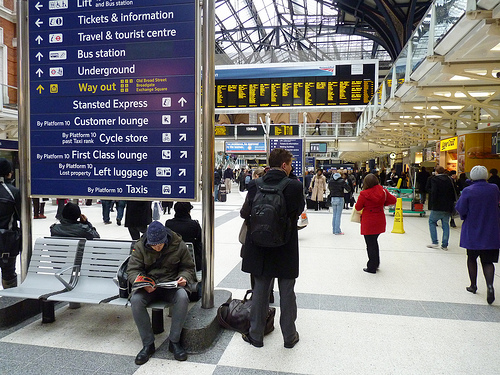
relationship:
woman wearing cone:
[351, 165, 399, 288] [390, 198, 405, 235]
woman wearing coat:
[449, 164, 497, 304] [456, 182, 498, 250]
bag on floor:
[217, 290, 275, 336] [4, 181, 497, 373]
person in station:
[453, 162, 497, 308] [2, 1, 499, 371]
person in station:
[239, 143, 309, 348] [2, 1, 499, 371]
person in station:
[121, 219, 194, 363] [2, 1, 499, 371]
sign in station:
[25, 2, 200, 200] [2, 1, 499, 371]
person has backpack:
[239, 146, 304, 349] [257, 182, 284, 233]